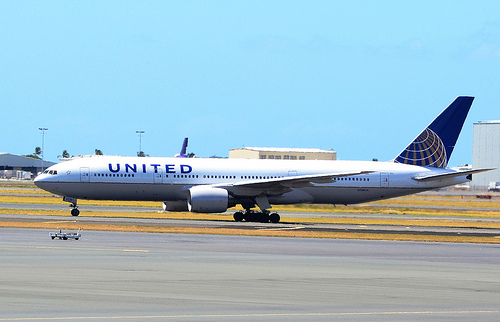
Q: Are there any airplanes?
A: Yes, there is an airplane.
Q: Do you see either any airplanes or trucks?
A: Yes, there is an airplane.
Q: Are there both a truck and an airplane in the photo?
A: No, there is an airplane but no trucks.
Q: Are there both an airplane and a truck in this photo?
A: No, there is an airplane but no trucks.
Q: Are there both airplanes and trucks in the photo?
A: No, there is an airplane but no trucks.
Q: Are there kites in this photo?
A: No, there are no kites.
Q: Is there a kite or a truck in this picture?
A: No, there are no kites or trucks.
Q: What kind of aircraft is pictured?
A: The aircraft is an airplane.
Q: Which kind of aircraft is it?
A: The aircraft is an airplane.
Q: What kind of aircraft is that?
A: This is an airplane.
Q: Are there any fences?
A: No, there are no fences.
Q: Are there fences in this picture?
A: No, there are no fences.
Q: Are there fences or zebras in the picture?
A: No, there are no fences or zebras.